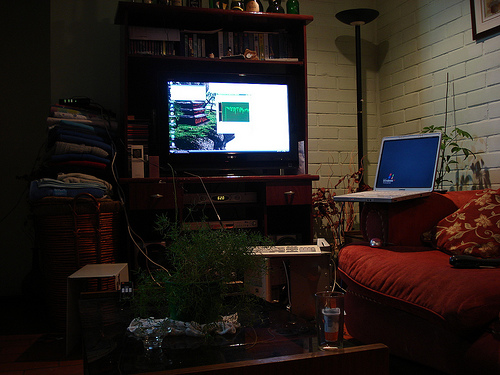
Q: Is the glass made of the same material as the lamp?
A: No, the glass is made of glass and the lamp is made of metal.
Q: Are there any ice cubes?
A: No, there are no ice cubes.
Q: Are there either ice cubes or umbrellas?
A: No, there are no ice cubes or umbrellas.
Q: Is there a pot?
A: Yes, there is a pot.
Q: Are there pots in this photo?
A: Yes, there is a pot.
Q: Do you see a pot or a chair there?
A: Yes, there is a pot.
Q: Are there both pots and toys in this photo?
A: No, there is a pot but no toys.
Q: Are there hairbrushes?
A: No, there are no hairbrushes.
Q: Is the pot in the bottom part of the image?
A: Yes, the pot is in the bottom of the image.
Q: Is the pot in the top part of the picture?
A: No, the pot is in the bottom of the image.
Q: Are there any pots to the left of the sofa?
A: Yes, there is a pot to the left of the sofa.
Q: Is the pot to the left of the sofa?
A: Yes, the pot is to the left of the sofa.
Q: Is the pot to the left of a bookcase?
A: No, the pot is to the left of the sofa.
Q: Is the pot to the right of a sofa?
A: No, the pot is to the left of a sofa.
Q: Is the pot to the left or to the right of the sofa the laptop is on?
A: The pot is to the left of the sofa.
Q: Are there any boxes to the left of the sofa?
A: Yes, there is a box to the left of the sofa.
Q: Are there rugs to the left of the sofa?
A: No, there is a box to the left of the sofa.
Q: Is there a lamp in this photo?
A: Yes, there is a lamp.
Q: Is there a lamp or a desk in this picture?
A: Yes, there is a lamp.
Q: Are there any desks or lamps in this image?
A: Yes, there is a lamp.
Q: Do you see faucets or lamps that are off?
A: Yes, the lamp is off.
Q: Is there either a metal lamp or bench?
A: Yes, there is a metal lamp.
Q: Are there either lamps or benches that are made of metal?
A: Yes, the lamp is made of metal.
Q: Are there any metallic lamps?
A: Yes, there is a metal lamp.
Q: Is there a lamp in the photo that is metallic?
A: Yes, there is a lamp that is metallic.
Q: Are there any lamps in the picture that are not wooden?
A: Yes, there is a metallic lamp.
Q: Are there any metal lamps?
A: Yes, there is a lamp that is made of metal.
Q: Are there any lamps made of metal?
A: Yes, there is a lamp that is made of metal.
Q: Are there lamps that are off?
A: Yes, there is a lamp that is off.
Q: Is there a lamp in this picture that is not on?
A: Yes, there is a lamp that is off.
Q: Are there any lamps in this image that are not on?
A: Yes, there is a lamp that is off.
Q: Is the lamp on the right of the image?
A: Yes, the lamp is on the right of the image.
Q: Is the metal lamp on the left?
A: No, the lamp is on the right of the image.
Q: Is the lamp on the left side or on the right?
A: The lamp is on the right of the image.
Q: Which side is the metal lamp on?
A: The lamp is on the right of the image.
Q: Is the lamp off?
A: Yes, the lamp is off.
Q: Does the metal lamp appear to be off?
A: Yes, the lamp is off.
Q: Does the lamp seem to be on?
A: No, the lamp is off.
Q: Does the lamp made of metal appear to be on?
A: No, the lamp is off.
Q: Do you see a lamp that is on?
A: No, there is a lamp but it is off.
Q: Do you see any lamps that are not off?
A: No, there is a lamp but it is off.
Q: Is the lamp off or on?
A: The lamp is off.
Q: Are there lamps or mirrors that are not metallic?
A: No, there is a lamp but it is metallic.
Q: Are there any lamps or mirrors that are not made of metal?
A: No, there is a lamp but it is made of metal.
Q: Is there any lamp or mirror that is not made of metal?
A: No, there is a lamp but it is made of metal.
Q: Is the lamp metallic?
A: Yes, the lamp is metallic.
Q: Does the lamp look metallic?
A: Yes, the lamp is metallic.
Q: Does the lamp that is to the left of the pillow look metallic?
A: Yes, the lamp is metallic.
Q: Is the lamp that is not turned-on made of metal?
A: Yes, the lamp is made of metal.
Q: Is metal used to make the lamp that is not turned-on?
A: Yes, the lamp is made of metal.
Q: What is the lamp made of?
A: The lamp is made of metal.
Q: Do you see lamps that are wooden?
A: No, there is a lamp but it is metallic.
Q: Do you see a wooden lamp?
A: No, there is a lamp but it is metallic.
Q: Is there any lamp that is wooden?
A: No, there is a lamp but it is metallic.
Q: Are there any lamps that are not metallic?
A: No, there is a lamp but it is metallic.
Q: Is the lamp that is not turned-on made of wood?
A: No, the lamp is made of metal.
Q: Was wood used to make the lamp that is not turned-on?
A: No, the lamp is made of metal.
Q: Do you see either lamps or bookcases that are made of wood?
A: No, there is a lamp but it is made of metal.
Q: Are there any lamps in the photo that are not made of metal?
A: No, there is a lamp but it is made of metal.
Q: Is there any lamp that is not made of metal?
A: No, there is a lamp but it is made of metal.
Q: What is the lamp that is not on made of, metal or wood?
A: The lamp is made of metal.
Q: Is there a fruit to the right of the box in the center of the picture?
A: No, there is a lamp to the right of the box.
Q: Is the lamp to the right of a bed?
A: No, the lamp is to the right of the box.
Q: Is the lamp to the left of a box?
A: No, the lamp is to the right of a box.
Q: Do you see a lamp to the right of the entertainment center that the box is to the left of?
A: Yes, there is a lamp to the right of the entertainment center.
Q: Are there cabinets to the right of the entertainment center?
A: No, there is a lamp to the right of the entertainment center.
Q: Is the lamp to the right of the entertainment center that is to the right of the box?
A: Yes, the lamp is to the right of the entertainment center.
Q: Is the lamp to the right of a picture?
A: No, the lamp is to the right of the entertainment center.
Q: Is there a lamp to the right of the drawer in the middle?
A: Yes, there is a lamp to the right of the drawer.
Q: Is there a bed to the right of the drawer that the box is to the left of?
A: No, there is a lamp to the right of the drawer.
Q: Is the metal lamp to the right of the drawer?
A: Yes, the lamp is to the right of the drawer.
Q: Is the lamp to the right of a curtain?
A: No, the lamp is to the right of the drawer.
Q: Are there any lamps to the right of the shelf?
A: Yes, there is a lamp to the right of the shelf.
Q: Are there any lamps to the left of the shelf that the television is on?
A: No, the lamp is to the right of the shelf.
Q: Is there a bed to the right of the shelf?
A: No, there is a lamp to the right of the shelf.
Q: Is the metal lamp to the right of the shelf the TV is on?
A: Yes, the lamp is to the right of the shelf.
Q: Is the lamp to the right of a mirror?
A: No, the lamp is to the right of the shelf.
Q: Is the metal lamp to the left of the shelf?
A: No, the lamp is to the right of the shelf.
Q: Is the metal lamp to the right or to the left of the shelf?
A: The lamp is to the right of the shelf.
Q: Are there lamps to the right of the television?
A: Yes, there is a lamp to the right of the television.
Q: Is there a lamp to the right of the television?
A: Yes, there is a lamp to the right of the television.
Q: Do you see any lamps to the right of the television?
A: Yes, there is a lamp to the right of the television.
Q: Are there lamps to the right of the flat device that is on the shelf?
A: Yes, there is a lamp to the right of the television.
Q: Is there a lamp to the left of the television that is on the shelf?
A: No, the lamp is to the right of the TV.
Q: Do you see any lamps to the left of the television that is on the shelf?
A: No, the lamp is to the right of the TV.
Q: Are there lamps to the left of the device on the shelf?
A: No, the lamp is to the right of the TV.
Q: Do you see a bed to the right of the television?
A: No, there is a lamp to the right of the television.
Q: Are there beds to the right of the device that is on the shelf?
A: No, there is a lamp to the right of the television.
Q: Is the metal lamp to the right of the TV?
A: Yes, the lamp is to the right of the TV.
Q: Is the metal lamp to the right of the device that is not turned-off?
A: Yes, the lamp is to the right of the TV.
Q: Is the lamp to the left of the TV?
A: No, the lamp is to the right of the TV.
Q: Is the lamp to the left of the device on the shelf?
A: No, the lamp is to the right of the TV.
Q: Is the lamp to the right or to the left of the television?
A: The lamp is to the right of the television.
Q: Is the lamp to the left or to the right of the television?
A: The lamp is to the right of the television.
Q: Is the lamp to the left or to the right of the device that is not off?
A: The lamp is to the right of the television.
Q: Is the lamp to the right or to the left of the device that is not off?
A: The lamp is to the right of the television.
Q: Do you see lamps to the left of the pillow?
A: Yes, there is a lamp to the left of the pillow.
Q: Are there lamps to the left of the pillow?
A: Yes, there is a lamp to the left of the pillow.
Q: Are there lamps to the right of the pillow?
A: No, the lamp is to the left of the pillow.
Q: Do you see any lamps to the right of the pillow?
A: No, the lamp is to the left of the pillow.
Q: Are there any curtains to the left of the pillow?
A: No, there is a lamp to the left of the pillow.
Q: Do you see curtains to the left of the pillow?
A: No, there is a lamp to the left of the pillow.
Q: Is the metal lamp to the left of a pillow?
A: Yes, the lamp is to the left of a pillow.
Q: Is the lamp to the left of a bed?
A: No, the lamp is to the left of a pillow.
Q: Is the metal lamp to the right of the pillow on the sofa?
A: No, the lamp is to the left of the pillow.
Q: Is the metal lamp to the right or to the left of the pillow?
A: The lamp is to the left of the pillow.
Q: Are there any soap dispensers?
A: No, there are no soap dispensers.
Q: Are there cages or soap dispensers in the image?
A: No, there are no soap dispensers or cages.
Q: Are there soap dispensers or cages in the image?
A: No, there are no soap dispensers or cages.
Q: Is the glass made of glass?
A: Yes, the glass is made of glass.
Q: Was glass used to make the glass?
A: Yes, the glass is made of glass.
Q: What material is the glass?
A: The glass is made of glass.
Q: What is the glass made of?
A: The glass is made of glass.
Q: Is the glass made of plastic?
A: No, the glass is made of glass.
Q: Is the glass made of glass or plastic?
A: The glass is made of glass.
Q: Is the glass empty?
A: Yes, the glass is empty.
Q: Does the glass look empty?
A: Yes, the glass is empty.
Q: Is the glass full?
A: No, the glass is empty.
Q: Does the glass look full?
A: No, the glass is empty.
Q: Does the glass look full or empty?
A: The glass is empty.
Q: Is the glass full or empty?
A: The glass is empty.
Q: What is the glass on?
A: The glass is on the table.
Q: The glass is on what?
A: The glass is on the table.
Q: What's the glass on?
A: The glass is on the table.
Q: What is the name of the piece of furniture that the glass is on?
A: The piece of furniture is a table.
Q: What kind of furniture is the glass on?
A: The glass is on the table.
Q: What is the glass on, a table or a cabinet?
A: The glass is on a table.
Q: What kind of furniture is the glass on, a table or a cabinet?
A: The glass is on a table.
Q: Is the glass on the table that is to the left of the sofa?
A: Yes, the glass is on the table.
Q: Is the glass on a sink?
A: No, the glass is on the table.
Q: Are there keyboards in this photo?
A: Yes, there is a keyboard.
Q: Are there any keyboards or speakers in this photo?
A: Yes, there is a keyboard.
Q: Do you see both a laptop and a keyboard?
A: Yes, there are both a keyboard and a laptop.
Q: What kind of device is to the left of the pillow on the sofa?
A: The device is a keyboard.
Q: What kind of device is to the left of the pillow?
A: The device is a keyboard.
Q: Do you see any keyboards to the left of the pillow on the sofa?
A: Yes, there is a keyboard to the left of the pillow.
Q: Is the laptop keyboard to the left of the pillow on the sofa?
A: Yes, the keyboard is to the left of the pillow.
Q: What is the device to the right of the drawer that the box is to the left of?
A: The device is a keyboard.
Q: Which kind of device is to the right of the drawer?
A: The device is a keyboard.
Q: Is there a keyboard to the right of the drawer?
A: Yes, there is a keyboard to the right of the drawer.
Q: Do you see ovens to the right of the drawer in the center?
A: No, there is a keyboard to the right of the drawer.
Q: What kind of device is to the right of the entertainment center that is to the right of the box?
A: The device is a keyboard.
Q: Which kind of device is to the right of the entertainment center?
A: The device is a keyboard.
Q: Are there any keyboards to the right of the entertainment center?
A: Yes, there is a keyboard to the right of the entertainment center.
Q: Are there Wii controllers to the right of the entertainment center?
A: No, there is a keyboard to the right of the entertainment center.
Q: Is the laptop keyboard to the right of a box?
A: Yes, the keyboard is to the right of a box.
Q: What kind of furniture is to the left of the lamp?
A: The piece of furniture is an entertainment center.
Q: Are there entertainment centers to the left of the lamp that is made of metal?
A: Yes, there is an entertainment center to the left of the lamp.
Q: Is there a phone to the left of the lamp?
A: No, there is an entertainment center to the left of the lamp.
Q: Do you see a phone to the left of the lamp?
A: No, there is an entertainment center to the left of the lamp.